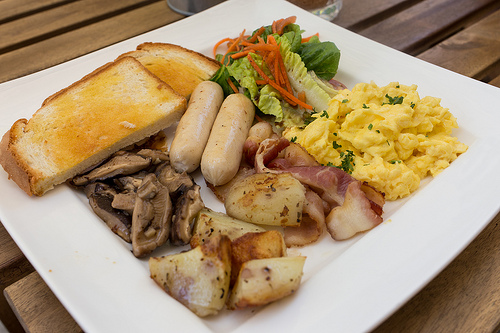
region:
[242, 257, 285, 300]
part of a potato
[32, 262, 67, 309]
edge of a dish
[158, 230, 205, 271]
edge of a dish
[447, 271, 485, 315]
part of a table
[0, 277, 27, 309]
edge of a wood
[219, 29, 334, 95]
salad greens with grated carrots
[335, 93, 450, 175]
scrambled eggs with herbs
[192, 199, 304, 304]
toasted red potatoes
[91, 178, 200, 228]
sauteed mushrooms on the plate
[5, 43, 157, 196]
toasted white bread with butter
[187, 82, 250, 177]
two grilled sausage links on the plate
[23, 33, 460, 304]
a healthy brunch being served on a square white plate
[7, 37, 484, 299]
a complete balanced meal served on a square white plate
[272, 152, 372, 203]
a strip of bacon on the plate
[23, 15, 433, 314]
a balanced meal of eggs, sausage links, tossed salad, roasted potatoes, bacon, sauteed mushrooms, and toast with butter.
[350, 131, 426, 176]
Yellow food on side of plate.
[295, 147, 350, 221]
Bacon strips on plate.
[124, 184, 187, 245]
Brown mushroom on plate.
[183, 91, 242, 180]
2 pieces of sausage on plate.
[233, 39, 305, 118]
Salad on corner of plate.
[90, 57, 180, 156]
Toast cut in half on plate.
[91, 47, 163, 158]
Toast cut in half on side of plate.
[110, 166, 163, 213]
Brown mushrooms on plate.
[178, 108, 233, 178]
2 sausage links on plate.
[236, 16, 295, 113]
Orange carrots on top of salad.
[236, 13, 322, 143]
Salad on corner of plate.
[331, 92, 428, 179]
Yellow food on side of plate.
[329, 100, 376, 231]
Green parsley on top of food.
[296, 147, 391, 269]
Pieces of bacon on plate.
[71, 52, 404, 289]
Food on top of white square plate.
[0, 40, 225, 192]
Piece of sliced bread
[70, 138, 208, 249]
Pieces of cooked meat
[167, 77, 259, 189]
Two pieces of sausages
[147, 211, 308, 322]
Pieces ofbaked potatoes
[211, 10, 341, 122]
Large pieces of vegetables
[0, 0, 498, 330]
White plate full of food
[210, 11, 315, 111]
Slices of carrots on top vegetables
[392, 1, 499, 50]
Brown colored table top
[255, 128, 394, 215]
Roasted strips of meat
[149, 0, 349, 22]
Glass sitting on the table